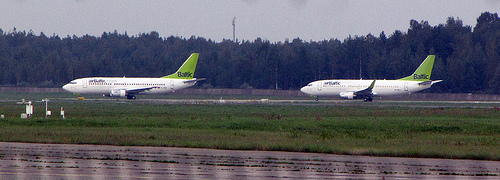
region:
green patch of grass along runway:
[82, 103, 494, 142]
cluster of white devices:
[20, 98, 74, 118]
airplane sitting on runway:
[299, 55, 443, 95]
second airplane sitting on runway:
[63, 52, 201, 104]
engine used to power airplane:
[112, 90, 127, 99]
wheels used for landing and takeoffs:
[126, 93, 144, 106]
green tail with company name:
[406, 47, 433, 82]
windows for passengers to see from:
[107, 80, 170, 88]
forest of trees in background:
[0, 27, 497, 52]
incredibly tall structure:
[230, 16, 240, 41]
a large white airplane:
[290, 55, 442, 107]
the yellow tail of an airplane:
[402, 43, 462, 94]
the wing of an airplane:
[97, 81, 145, 102]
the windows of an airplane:
[80, 78, 115, 98]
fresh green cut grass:
[244, 101, 326, 149]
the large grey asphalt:
[72, 143, 139, 178]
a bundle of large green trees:
[210, 28, 277, 80]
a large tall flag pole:
[225, 6, 247, 44]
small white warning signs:
[11, 97, 75, 124]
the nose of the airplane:
[297, 74, 315, 99]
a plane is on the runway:
[62, 52, 199, 97]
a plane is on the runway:
[299, 56, 436, 101]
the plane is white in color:
[65, 75, 197, 98]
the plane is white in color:
[300, 76, 437, 101]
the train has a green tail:
[160, 48, 200, 79]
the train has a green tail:
[406, 52, 436, 80]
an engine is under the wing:
[107, 88, 127, 97]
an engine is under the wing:
[343, 90, 365, 100]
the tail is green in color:
[167, 53, 202, 80]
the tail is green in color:
[402, 55, 437, 79]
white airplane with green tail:
[293, 53, 465, 101]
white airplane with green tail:
[53, 37, 220, 114]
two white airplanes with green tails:
[51, 42, 458, 114]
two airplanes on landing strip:
[56, 42, 452, 113]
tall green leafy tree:
[285, 35, 300, 90]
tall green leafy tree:
[336, 34, 363, 83]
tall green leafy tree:
[364, 33, 394, 73]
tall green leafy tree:
[401, 13, 431, 73]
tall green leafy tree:
[442, 14, 479, 91]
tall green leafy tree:
[470, 10, 497, 77]